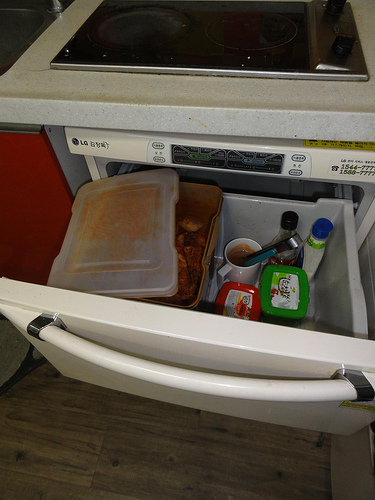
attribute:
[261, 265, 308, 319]
container — green, plastic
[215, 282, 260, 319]
top — red, plastic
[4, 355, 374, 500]
floor — dark, brown, wooden, laminate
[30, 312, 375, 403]
handle — white, stove handle, curved, silver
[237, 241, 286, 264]
utensil — blue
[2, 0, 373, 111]
top — counter top, white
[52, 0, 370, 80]
cooktop — dirt, metal, silver, black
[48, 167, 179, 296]
top — plastic, clear, white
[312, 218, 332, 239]
cap — blue, bottle cap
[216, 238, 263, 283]
mug — white, dirty, coffee mug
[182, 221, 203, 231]
meat — cooked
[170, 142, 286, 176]
panel — black, dark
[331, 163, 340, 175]
symbol — telephone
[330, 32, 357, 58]
knob — black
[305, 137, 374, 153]
sticker — yellow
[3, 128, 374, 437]
fridge — gross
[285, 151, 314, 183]
buttons — here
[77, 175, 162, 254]
sauce — leftover